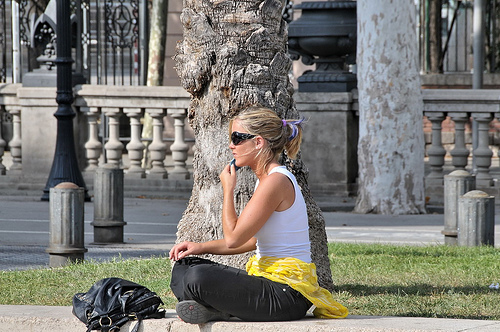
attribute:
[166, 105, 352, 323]
woman — seated, blonde, on her cell phone, sitting, talking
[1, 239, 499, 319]
grass — green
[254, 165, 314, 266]
shirt — white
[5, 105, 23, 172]
pillar — cement, stone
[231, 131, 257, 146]
sunglasses — black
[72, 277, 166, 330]
handbag — black, in front of woman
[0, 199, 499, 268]
road — tarmac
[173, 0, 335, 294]
tree trunk — wide, tall, large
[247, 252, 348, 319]
jacket — yellow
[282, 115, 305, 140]
hair tie — purple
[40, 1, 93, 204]
lamp post — black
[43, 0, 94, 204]
pole — decorative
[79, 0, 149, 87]
gate — iron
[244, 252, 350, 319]
clothing — around woman's waist